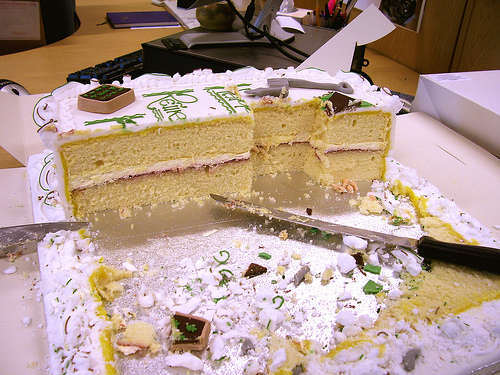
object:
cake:
[55, 76, 396, 221]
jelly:
[73, 153, 250, 188]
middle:
[65, 150, 254, 190]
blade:
[208, 190, 414, 251]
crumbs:
[174, 296, 202, 317]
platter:
[19, 67, 500, 375]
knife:
[207, 193, 499, 276]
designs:
[143, 88, 198, 122]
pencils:
[344, 0, 355, 17]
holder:
[295, 4, 395, 73]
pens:
[315, 5, 322, 26]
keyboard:
[65, 46, 172, 83]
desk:
[0, 0, 500, 375]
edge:
[379, 111, 394, 181]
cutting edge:
[213, 199, 416, 251]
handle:
[416, 235, 499, 276]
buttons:
[103, 68, 125, 79]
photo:
[0, 2, 497, 375]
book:
[106, 10, 180, 28]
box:
[410, 70, 498, 157]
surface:
[0, 0, 186, 95]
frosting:
[142, 80, 251, 124]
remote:
[160, 38, 188, 51]